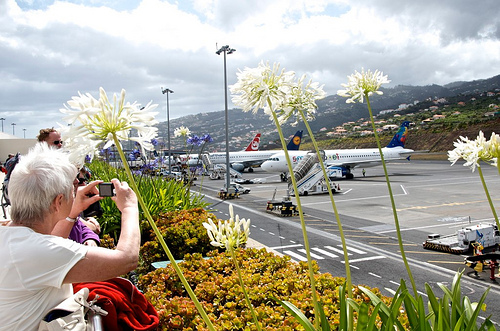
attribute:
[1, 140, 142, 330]
person — taking picture, taking photograph, elderly, older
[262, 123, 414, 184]
airplane — white, at airport, parked, metal, large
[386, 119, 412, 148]
tail — blue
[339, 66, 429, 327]
flowers — white, taill, small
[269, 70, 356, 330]
flowers — white, tall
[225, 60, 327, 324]
flowers — white, tall, large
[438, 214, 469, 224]
paint — white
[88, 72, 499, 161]
hill — distance, next to airport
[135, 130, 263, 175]
airplane — white, parked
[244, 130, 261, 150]
tail — white, red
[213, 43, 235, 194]
post — large, light, metal, tall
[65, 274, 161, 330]
jacket — red, draped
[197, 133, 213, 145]
flower — blue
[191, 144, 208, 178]
stems — green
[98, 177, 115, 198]
cellphone — small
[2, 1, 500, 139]
sky — cloudy, dark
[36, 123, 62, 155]
people — watching, standing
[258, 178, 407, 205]
lines — white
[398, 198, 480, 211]
lines — yellow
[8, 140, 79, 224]
hair — white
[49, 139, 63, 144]
sunglasses — black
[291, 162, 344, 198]
truck — large